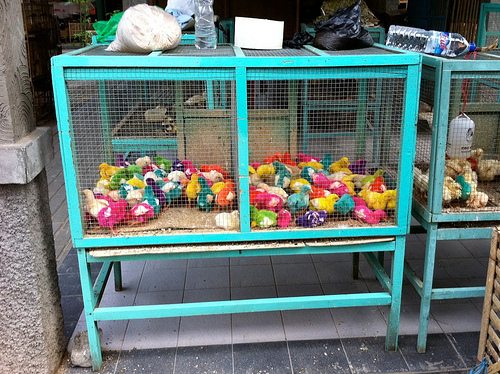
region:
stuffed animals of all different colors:
[82, 136, 399, 226]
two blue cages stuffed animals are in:
[44, 41, 493, 364]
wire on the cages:
[73, 73, 490, 227]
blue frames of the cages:
[51, 38, 498, 361]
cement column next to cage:
[3, 4, 70, 372]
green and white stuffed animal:
[248, 203, 280, 231]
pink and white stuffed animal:
[128, 198, 151, 221]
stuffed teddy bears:
[427, 146, 497, 211]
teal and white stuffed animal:
[196, 176, 211, 206]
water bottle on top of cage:
[192, 3, 220, 50]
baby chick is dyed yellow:
[317, 198, 337, 221]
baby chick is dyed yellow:
[366, 185, 391, 211]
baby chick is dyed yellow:
[343, 173, 353, 190]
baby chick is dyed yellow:
[335, 158, 350, 173]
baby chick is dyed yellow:
[294, 168, 309, 195]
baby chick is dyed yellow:
[188, 172, 207, 200]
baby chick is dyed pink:
[353, 201, 379, 226]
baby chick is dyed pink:
[266, 194, 288, 216]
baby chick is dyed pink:
[129, 199, 152, 219]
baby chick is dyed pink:
[97, 203, 129, 225]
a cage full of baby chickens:
[58, 55, 420, 242]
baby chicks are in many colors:
[256, 178, 358, 226]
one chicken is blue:
[286, 183, 314, 210]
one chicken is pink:
[355, 206, 387, 220]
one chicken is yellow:
[186, 173, 201, 201]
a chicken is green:
[111, 165, 130, 180]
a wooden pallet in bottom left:
[479, 227, 499, 372]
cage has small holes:
[302, 130, 380, 162]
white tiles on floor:
[218, 263, 277, 295]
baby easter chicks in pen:
[110, 131, 382, 223]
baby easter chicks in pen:
[122, 150, 373, 231]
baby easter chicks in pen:
[121, 150, 357, 227]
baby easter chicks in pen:
[128, 155, 351, 225]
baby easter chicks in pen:
[117, 151, 325, 224]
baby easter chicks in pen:
[140, 152, 367, 219]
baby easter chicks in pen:
[198, 168, 342, 223]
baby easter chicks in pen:
[287, 164, 344, 216]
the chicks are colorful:
[87, 138, 385, 242]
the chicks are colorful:
[57, 130, 384, 233]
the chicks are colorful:
[68, 142, 407, 227]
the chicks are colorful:
[71, 153, 388, 223]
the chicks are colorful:
[79, 147, 399, 233]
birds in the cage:
[64, 130, 405, 238]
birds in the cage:
[85, 152, 397, 237]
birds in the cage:
[78, 147, 410, 233]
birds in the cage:
[64, 145, 399, 245]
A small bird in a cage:
[81, 184, 108, 214]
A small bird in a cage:
[216, 209, 241, 229]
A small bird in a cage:
[125, 189, 142, 207]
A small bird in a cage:
[136, 154, 150, 168]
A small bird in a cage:
[99, 197, 127, 232]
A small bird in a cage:
[123, 203, 154, 227]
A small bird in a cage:
[177, 158, 197, 174]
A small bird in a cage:
[351, 204, 388, 224]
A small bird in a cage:
[276, 207, 293, 228]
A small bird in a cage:
[256, 192, 283, 209]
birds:
[86, 183, 162, 226]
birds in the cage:
[103, 151, 170, 217]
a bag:
[319, 13, 366, 48]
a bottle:
[388, 23, 473, 60]